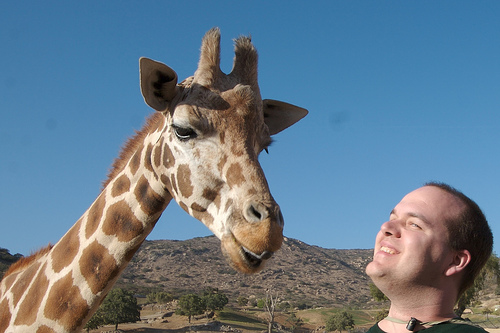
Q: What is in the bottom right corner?
A: Human male.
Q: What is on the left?
A: Giraffe.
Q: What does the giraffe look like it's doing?
A: Smiling.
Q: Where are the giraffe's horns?
A: On its head.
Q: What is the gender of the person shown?
A: Male.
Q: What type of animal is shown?
A: Giraffe.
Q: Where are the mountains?
A: Behind the man.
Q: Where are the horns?
A: On the giraffe.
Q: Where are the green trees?
A: In brown grass field.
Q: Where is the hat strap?
A: Around man's neck.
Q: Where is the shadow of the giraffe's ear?
A: On giraffe's face.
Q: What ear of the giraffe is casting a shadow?
A: Right.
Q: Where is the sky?
A: Above the mountains.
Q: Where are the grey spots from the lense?
A: Sky.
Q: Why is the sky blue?
A: No clouds.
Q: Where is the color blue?
A: In the sky.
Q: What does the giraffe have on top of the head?
A: Ears.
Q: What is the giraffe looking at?
A: The man.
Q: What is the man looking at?
A: The giraffe.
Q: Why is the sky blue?
A: It is daytime.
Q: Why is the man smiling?
A: Because he is looking at the giraffe.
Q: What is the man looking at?
A: A giraffe?.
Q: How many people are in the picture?
A: One.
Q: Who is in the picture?
A: The man.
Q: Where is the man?
A: On right.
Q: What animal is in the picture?
A: Giraffe.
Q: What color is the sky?
A: Blue.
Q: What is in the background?
A: Mountains.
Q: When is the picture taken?
A: Day time.